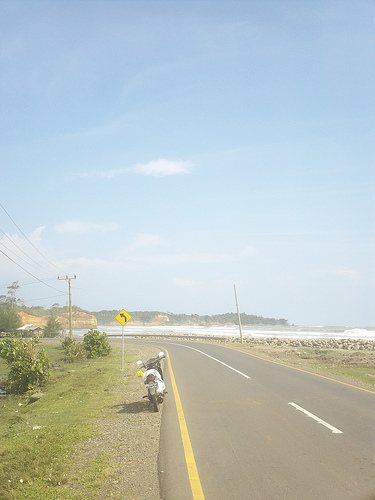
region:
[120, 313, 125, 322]
A road sign by the road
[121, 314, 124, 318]
The arrow on the road sign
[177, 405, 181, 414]
A yellow line on the side of the road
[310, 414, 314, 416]
A white line in the middle of the road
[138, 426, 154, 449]
Gravel by the roadside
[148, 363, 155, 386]
A motorbike parked on the side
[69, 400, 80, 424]
Grass on the ground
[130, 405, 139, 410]
Shadow cast by the motorbike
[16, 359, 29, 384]
Bush by the road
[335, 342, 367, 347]
A wall of stacked stones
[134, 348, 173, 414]
white motorcycle parked by a road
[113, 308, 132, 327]
yellow sign indicating an upcoming curve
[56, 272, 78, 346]
tall wooden power pole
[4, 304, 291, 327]
low hills along the horizon line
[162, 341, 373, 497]
a short stretch of blacktop highway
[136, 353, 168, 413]
motorcycle parked on the shoulder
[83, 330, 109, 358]
leafy green bush by the road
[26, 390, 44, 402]
flat grey rock lying on the ground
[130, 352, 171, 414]
motorcycle parked in the gravel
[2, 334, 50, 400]
bent leafy bush growing in the dirt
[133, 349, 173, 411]
MOTORCYCLE ON SIDE OF ROAD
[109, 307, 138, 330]
ROAD SIGN WARNING OF CURVE IN ROAD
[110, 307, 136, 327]
ROAD SIGN IS DIAMOND SHAPED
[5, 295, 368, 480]
THIS AREA IS RURAL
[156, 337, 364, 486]
TWO LANE HIGHWAY WITH NO VISIBLE TRAFFIC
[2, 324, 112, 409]
BUSHES IN GRASS AT SIDE OF ROAD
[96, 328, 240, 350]
GUARD RAIL AT WATERS EDGE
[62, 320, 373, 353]
LAKE IS IN THE BACKGROUND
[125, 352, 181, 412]
MOTORCYCLE RIDER IS NOT SEEN IN PHOTO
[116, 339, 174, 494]
SHOULDER OF ROAD IS DIRT AND GRAVEL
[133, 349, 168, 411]
a white motorcycle on the side of the road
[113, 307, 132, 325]
a yellow and black sign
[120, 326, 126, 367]
a metal pole in the ground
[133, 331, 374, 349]
a large group of rocks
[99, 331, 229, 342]
some guard rails next to the road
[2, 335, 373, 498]
an asphalt road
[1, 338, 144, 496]
a grassy landscape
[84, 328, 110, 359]
A small, full bush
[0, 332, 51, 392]
A small, full bush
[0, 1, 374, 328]
a clear, blue sky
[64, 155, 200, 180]
The cloud is white and faint.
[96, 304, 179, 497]
The motorcycle is parked alongside the road.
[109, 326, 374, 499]
The road has yellow lines painted on each side.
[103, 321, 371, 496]
The road has white lines painted down the middle.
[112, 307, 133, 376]
The sign is black and yellow.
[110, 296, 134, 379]
The arrow on the sign is black.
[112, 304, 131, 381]
The sign has an arrow on it.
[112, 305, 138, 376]
The signpost is gray.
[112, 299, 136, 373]
The signpost is metal.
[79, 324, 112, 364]
The bush is green.